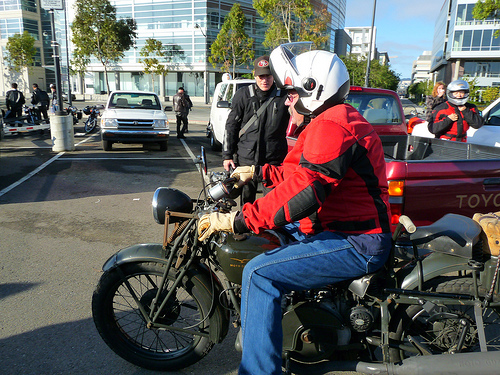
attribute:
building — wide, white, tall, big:
[3, 1, 352, 88]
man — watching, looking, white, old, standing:
[236, 57, 284, 161]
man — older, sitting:
[279, 54, 392, 267]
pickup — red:
[349, 88, 484, 206]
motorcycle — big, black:
[90, 187, 481, 363]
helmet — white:
[258, 33, 356, 109]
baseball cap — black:
[250, 57, 270, 76]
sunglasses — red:
[282, 82, 299, 104]